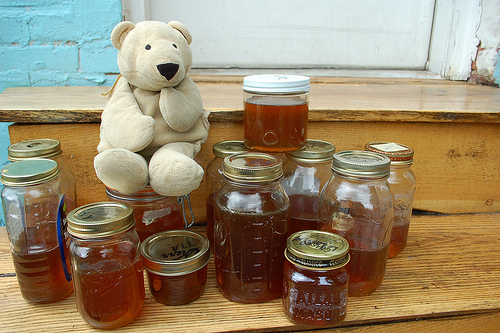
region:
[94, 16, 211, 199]
a light brown bear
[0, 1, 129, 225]
a blue painted brick wall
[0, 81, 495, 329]
brown wooden steps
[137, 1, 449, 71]
a white door at the top of steps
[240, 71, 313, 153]
a white lid on a jar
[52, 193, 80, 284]
a blue label on a jar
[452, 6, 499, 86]
a crumbling white door frame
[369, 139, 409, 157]
a white paper label on a jar lid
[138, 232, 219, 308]
a small jar of honey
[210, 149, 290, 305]
a large jar of honey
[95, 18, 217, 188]
The teddy bear is white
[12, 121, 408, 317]
The jars are full of honey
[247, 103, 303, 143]
The honey is orange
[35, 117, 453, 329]
The honey is on the counter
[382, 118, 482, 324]
The counter is made of wood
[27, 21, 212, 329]
The teddy bear sits on the jars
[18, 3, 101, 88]
The wall is blue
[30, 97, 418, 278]
Each of the jars are sealed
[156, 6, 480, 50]
The window pane is white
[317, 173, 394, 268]
This jar is half full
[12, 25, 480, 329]
Toy bear and bottles on counter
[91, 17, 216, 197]
Toy black and white bear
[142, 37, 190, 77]
Black eyes and nose on stuffed bear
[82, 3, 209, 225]
Stuffed bear sitting on jar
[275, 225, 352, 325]
Filled Mason jar with liquid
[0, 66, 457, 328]
Mason jars filled with brown liquid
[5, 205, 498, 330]
Grainy brown wooden counter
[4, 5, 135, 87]
Blue painted brick wall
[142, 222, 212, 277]
Top of mason jar with writing on top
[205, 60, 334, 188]
White capped jar sitting atop of jars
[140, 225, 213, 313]
half pint canning jar with honey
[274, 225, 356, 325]
pint jar filled with honey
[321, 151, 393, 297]
quart jar filled one third with honey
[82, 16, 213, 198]
beige teddy bear sitting on jar of honey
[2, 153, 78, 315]
rounded jar , honey comb shaped, half filled with honey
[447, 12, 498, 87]
peeling, cracked old paint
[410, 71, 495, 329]
wooden steps near outside door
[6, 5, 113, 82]
old peeling light blue pain on bricks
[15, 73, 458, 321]
twelve jars with honey of various sizes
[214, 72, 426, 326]
the jars have honey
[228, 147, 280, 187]
the lid is silver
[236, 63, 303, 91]
the lid is white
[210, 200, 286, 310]
honey is in the jar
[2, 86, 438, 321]
the jars are eleven in total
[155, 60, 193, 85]
the nose is black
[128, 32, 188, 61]
the eyes are black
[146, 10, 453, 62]
the window is white